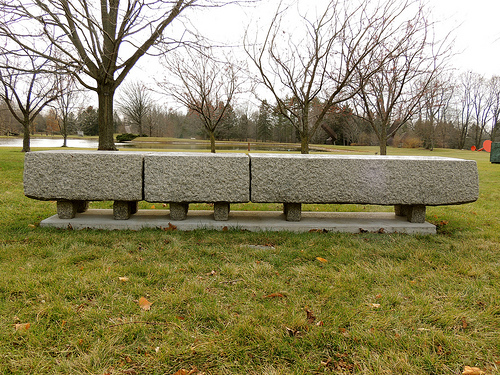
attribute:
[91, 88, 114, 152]
treetrunk — brown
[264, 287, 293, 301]
leaf — brown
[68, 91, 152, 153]
trunk — brown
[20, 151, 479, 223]
bench — stone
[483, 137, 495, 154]
object — red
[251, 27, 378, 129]
tree — barren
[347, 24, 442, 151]
tree — barren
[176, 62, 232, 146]
tree — barren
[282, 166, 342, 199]
structure — grey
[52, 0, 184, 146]
tree — barren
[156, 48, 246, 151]
tree — barren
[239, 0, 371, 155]
tree — barren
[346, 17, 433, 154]
tree — barren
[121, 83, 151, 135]
tree — barren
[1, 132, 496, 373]
field — grassy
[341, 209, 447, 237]
slab — stone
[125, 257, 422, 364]
grass — green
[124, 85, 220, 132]
tree — barren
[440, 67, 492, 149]
tree — barren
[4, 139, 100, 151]
ground — paved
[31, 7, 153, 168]
tree — bare, brown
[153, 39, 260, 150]
tree — barren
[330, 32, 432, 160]
tree — barren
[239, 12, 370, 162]
tree — barren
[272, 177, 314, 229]
leg — stone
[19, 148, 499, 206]
stone — large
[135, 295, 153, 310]
leaf — brown 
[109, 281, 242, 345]
grass — short